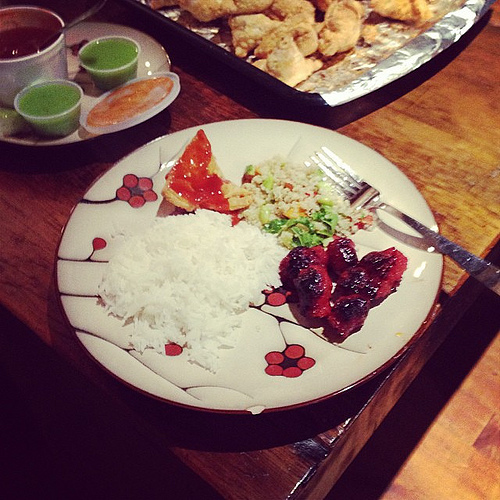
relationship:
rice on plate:
[95, 208, 288, 376] [57, 117, 451, 411]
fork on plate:
[303, 145, 498, 297] [57, 117, 451, 411]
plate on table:
[57, 117, 451, 411] [1, 2, 498, 498]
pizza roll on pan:
[263, 35, 309, 86] [145, 4, 492, 124]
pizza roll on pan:
[315, 0, 363, 57] [145, 4, 492, 124]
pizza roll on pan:
[369, 0, 432, 20] [145, 4, 492, 124]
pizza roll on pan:
[226, 15, 275, 60] [145, 4, 492, 124]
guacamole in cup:
[8, 76, 83, 137] [80, 36, 138, 87]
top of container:
[74, 62, 191, 144] [1, 9, 83, 108]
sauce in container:
[2, 23, 61, 56] [0, 4, 67, 104]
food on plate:
[99, 129, 409, 359] [57, 117, 451, 411]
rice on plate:
[95, 196, 289, 368] [31, 105, 451, 424]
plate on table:
[265, 133, 280, 145] [1, 2, 498, 498]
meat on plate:
[286, 239, 406, 343] [57, 117, 451, 411]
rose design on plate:
[103, 163, 152, 220] [57, 117, 451, 411]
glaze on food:
[286, 246, 321, 305] [280, 236, 407, 336]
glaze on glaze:
[335, 241, 392, 321] [286, 246, 321, 305]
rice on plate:
[95, 208, 288, 376] [236, 322, 330, 398]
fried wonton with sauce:
[164, 123, 251, 217] [169, 130, 229, 208]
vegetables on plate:
[246, 155, 343, 245] [57, 117, 488, 426]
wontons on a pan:
[178, 3, 430, 82] [121, 0, 488, 122]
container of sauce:
[13, 76, 81, 137] [16, 81, 80, 138]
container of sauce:
[76, 33, 141, 91] [80, 37, 138, 90]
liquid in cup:
[26, 85, 79, 116] [13, 78, 84, 139]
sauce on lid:
[84, 75, 175, 125] [72, 62, 184, 137]